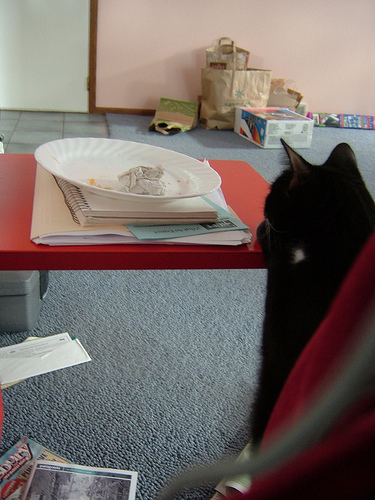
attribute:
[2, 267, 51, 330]
safe — gray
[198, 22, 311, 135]
bag — brown